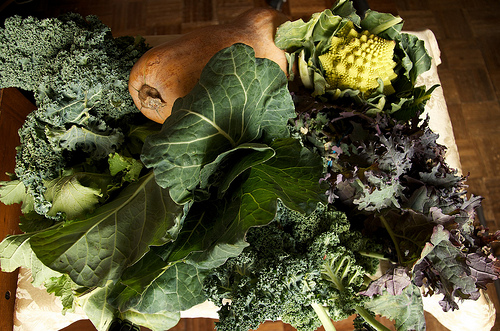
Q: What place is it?
A: It is a garden.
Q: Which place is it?
A: It is a garden.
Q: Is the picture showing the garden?
A: Yes, it is showing the garden.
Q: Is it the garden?
A: Yes, it is the garden.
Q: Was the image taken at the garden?
A: Yes, it was taken in the garden.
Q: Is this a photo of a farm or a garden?
A: It is showing a garden.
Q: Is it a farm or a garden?
A: It is a garden.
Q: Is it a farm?
A: No, it is a garden.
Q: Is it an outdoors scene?
A: Yes, it is outdoors.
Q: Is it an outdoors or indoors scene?
A: It is outdoors.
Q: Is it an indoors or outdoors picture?
A: It is outdoors.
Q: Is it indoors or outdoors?
A: It is outdoors.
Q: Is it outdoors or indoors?
A: It is outdoors.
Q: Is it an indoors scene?
A: No, it is outdoors.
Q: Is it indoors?
A: No, it is outdoors.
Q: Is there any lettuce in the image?
A: Yes, there is lettuce.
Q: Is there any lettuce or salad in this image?
A: Yes, there is lettuce.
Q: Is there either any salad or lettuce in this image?
A: Yes, there is lettuce.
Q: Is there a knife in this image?
A: No, there are no knives.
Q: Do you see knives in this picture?
A: No, there are no knives.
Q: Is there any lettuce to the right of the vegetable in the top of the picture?
A: No, the lettuce is to the left of the vegetable.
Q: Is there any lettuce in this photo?
A: Yes, there is lettuce.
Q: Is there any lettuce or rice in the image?
A: Yes, there is lettuce.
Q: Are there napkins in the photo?
A: No, there are no napkins.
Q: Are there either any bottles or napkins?
A: No, there are no napkins or bottles.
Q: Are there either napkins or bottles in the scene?
A: No, there are no napkins or bottles.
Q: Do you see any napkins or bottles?
A: No, there are no napkins or bottles.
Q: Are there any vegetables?
A: Yes, there are vegetables.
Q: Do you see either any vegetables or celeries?
A: Yes, there are vegetables.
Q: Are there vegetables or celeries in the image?
A: Yes, there are vegetables.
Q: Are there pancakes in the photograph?
A: No, there are no pancakes.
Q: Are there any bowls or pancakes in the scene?
A: No, there are no pancakes or bowls.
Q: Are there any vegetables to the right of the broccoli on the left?
A: Yes, there are vegetables to the right of the broccoli.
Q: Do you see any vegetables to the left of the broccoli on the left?
A: No, the vegetables are to the right of the broccoli.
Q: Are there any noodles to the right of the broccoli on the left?
A: No, there are vegetables to the right of the broccoli.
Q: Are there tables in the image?
A: Yes, there is a table.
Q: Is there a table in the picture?
A: Yes, there is a table.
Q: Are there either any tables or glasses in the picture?
A: Yes, there is a table.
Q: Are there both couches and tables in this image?
A: No, there is a table but no couches.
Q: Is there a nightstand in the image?
A: No, there are no nightstands.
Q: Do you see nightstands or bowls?
A: No, there are no nightstands or bowls.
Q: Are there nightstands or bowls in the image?
A: No, there are no nightstands or bowls.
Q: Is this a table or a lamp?
A: This is a table.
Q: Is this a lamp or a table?
A: This is a table.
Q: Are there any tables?
A: Yes, there is a table.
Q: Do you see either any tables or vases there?
A: Yes, there is a table.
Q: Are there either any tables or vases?
A: Yes, there is a table.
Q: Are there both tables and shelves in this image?
A: No, there is a table but no shelves.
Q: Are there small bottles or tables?
A: Yes, there is a small table.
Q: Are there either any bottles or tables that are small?
A: Yes, the table is small.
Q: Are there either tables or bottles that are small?
A: Yes, the table is small.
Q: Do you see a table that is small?
A: Yes, there is a small table.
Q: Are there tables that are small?
A: Yes, there is a table that is small.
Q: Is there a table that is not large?
A: Yes, there is a small table.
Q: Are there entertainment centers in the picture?
A: No, there are no entertainment centers.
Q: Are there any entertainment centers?
A: No, there are no entertainment centers.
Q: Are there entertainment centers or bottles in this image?
A: No, there are no entertainment centers or bottles.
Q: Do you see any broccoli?
A: Yes, there is broccoli.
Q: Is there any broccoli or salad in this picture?
A: Yes, there is broccoli.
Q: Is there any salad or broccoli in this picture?
A: Yes, there is broccoli.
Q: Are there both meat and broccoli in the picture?
A: No, there is broccoli but no meat.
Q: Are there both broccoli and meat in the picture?
A: No, there is broccoli but no meat.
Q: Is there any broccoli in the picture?
A: Yes, there is broccoli.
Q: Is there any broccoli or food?
A: Yes, there is broccoli.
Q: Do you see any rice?
A: No, there is no rice.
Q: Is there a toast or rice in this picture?
A: No, there are no rice or toasts.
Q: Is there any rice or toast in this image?
A: No, there are no rice or toasts.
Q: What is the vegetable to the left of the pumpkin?
A: The vegetable is broccoli.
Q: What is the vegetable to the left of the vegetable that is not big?
A: The vegetable is broccoli.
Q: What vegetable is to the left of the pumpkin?
A: The vegetable is broccoli.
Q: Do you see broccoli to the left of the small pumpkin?
A: Yes, there is broccoli to the left of the pumpkin.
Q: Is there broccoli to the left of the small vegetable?
A: Yes, there is broccoli to the left of the pumpkin.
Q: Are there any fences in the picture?
A: No, there are no fences.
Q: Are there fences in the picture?
A: No, there are no fences.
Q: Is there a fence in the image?
A: No, there are no fences.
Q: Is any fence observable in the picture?
A: No, there are no fences.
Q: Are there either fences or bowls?
A: No, there are no fences or bowls.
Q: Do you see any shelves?
A: No, there are no shelves.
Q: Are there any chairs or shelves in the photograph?
A: No, there are no shelves or chairs.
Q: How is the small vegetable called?
A: The vegetable is a pumpkin.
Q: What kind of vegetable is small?
A: The vegetable is a pumpkin.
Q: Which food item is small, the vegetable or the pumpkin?
A: The pumpkin is small.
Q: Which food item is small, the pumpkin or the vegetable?
A: The pumpkin is small.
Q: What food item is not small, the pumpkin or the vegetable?
A: The vegetable is not small.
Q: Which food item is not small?
A: The food item is a vegetable.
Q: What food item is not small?
A: The food item is a vegetable.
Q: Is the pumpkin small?
A: Yes, the pumpkin is small.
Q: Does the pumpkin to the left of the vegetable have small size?
A: Yes, the pumpkin is small.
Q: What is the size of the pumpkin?
A: The pumpkin is small.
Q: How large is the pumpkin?
A: The pumpkin is small.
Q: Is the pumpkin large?
A: No, the pumpkin is small.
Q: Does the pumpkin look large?
A: No, the pumpkin is small.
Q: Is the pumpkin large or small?
A: The pumpkin is small.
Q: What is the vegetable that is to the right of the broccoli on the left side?
A: The vegetable is a pumpkin.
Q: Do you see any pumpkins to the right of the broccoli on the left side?
A: Yes, there is a pumpkin to the right of the broccoli.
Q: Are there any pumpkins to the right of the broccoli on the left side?
A: Yes, there is a pumpkin to the right of the broccoli.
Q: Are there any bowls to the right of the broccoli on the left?
A: No, there is a pumpkin to the right of the broccoli.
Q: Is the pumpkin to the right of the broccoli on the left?
A: Yes, the pumpkin is to the right of the broccoli.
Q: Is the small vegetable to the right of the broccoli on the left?
A: Yes, the pumpkin is to the right of the broccoli.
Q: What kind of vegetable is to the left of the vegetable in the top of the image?
A: The vegetable is a pumpkin.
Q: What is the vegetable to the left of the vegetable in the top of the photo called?
A: The vegetable is a pumpkin.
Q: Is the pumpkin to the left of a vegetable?
A: Yes, the pumpkin is to the left of a vegetable.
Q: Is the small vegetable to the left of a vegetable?
A: Yes, the pumpkin is to the left of a vegetable.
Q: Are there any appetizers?
A: No, there are no appetizers.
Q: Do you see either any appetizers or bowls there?
A: No, there are no appetizers or bowls.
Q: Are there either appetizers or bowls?
A: No, there are no appetizers or bowls.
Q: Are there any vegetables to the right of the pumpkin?
A: Yes, there is a vegetable to the right of the pumpkin.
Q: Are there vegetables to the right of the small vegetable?
A: Yes, there is a vegetable to the right of the pumpkin.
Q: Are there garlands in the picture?
A: No, there are no garlands.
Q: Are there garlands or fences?
A: No, there are no garlands or fences.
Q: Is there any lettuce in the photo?
A: Yes, there is lettuce.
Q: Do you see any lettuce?
A: Yes, there is lettuce.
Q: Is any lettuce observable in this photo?
A: Yes, there is lettuce.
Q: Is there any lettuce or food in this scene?
A: Yes, there is lettuce.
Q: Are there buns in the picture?
A: No, there are no buns.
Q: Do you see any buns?
A: No, there are no buns.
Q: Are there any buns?
A: No, there are no buns.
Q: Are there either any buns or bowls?
A: No, there are no buns or bowls.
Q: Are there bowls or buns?
A: No, there are no buns or bowls.